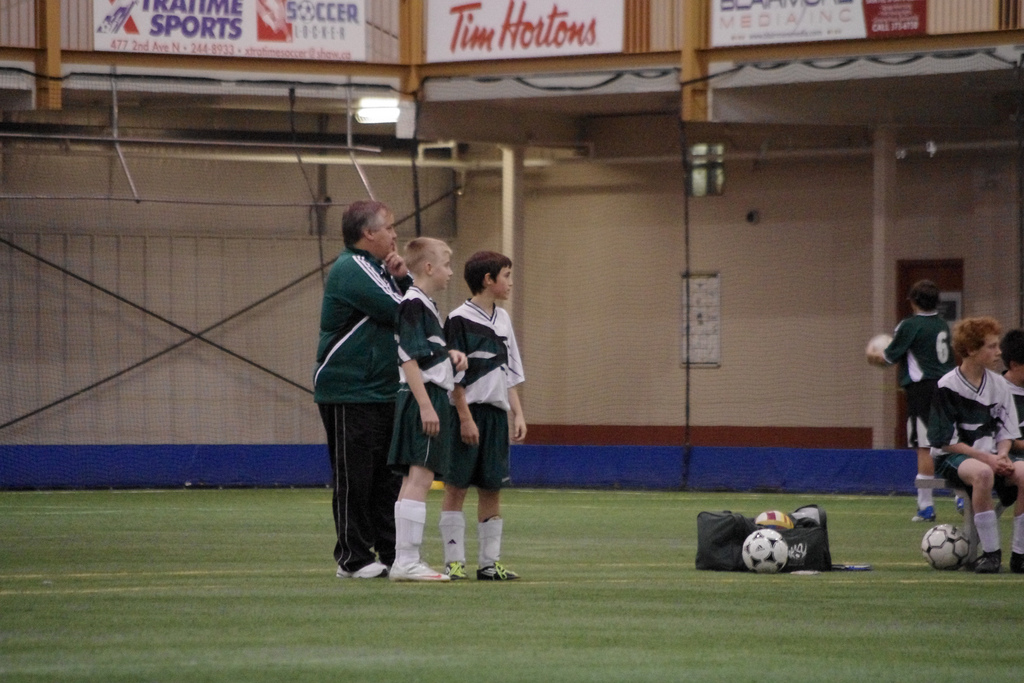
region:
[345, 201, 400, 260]
player has a head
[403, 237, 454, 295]
player has a head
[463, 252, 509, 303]
player has a head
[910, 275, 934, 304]
player has a head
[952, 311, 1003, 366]
player has a head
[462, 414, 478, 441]
player has a hand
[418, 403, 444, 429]
player has a hand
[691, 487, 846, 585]
the bag on the ground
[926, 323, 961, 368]
the six on the jersey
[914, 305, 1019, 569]
the boy is sitting down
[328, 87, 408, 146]
the light is on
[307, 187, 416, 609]
the man is watching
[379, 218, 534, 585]
the boys wearing shorts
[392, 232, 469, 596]
the boy has blonde hair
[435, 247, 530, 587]
the boy has dark hair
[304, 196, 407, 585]
man wearing a green shirt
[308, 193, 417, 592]
man wearing black athletic pants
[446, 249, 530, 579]
boy wearing a white and green shirt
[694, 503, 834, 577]
soccer ball on the ground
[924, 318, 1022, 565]
athlete sitting on a bench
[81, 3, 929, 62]
advertising signs on a wall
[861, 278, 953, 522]
boy holding a soccer ball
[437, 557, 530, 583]
sneakers with green shoelaces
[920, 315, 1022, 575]
boy with red hair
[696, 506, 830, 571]
the black bag has soccer balls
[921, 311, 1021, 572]
the ginger boy is sitting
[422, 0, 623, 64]
the sign is white and red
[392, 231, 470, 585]
the kid's uniform is white and green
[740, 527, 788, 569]
the soccer ball is black and white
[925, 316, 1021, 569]
the boy is sitting down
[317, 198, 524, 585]
the man standing near two boys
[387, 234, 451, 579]
the boy has blonde hair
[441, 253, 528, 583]
the boy has brown hair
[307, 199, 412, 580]
the man is wearing a green and white jacket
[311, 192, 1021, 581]
the people are dressed in soccer uniforms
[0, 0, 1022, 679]
the people at the soccer field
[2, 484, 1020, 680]
the grass is green and short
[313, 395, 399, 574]
the pants are black with thin white stripes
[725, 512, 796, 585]
A black and white soccer ball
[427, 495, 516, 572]
A pair of long white socks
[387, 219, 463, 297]
Boy has blonde hair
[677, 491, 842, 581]
A soccer ball in a black bag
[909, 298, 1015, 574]
A boy is sitting down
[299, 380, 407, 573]
White stripes on black pants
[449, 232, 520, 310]
Boy has brown hair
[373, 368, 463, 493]
A pair of green shorts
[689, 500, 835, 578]
bag of soccer balls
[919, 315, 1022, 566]
boy sitting near a soccer ball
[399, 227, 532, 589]
two boys in green and white uniforms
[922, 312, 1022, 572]
athlete with red hair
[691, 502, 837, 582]
soccer ball near a black bag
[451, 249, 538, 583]
boy with brown hair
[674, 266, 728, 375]
white poster on a wall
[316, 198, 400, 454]
a person standing on the field